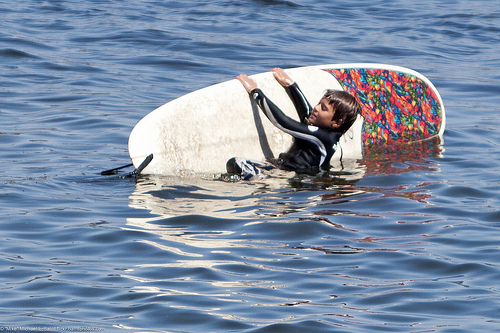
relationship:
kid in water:
[235, 65, 365, 167] [3, 2, 499, 332]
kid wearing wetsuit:
[235, 65, 365, 167] [249, 129, 334, 181]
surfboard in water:
[113, 62, 452, 161] [3, 2, 499, 332]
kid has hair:
[235, 65, 365, 167] [321, 89, 358, 130]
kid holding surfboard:
[235, 65, 365, 167] [113, 62, 452, 161]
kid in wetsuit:
[235, 65, 365, 167] [249, 129, 334, 181]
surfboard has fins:
[113, 62, 452, 161] [103, 155, 169, 178]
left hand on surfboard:
[234, 75, 260, 92] [113, 62, 452, 161]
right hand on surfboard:
[271, 66, 302, 91] [113, 62, 452, 161]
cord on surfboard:
[124, 162, 203, 178] [113, 62, 452, 161]